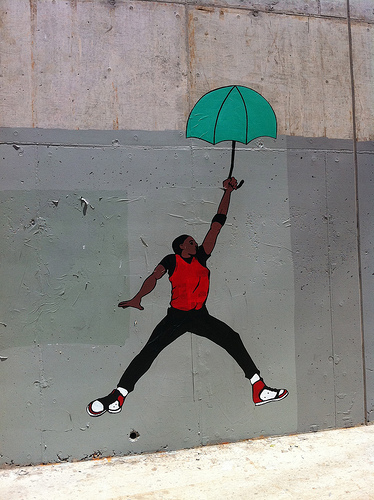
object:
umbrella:
[184, 84, 280, 144]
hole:
[129, 430, 139, 442]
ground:
[55, 459, 301, 497]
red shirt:
[169, 253, 208, 310]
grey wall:
[299, 206, 362, 333]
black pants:
[116, 308, 260, 394]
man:
[86, 176, 291, 419]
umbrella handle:
[227, 163, 246, 191]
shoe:
[250, 377, 289, 406]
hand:
[116, 297, 144, 312]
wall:
[3, 0, 355, 426]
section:
[12, 356, 100, 388]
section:
[82, 165, 183, 221]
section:
[238, 282, 270, 328]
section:
[258, 327, 297, 364]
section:
[338, 295, 373, 372]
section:
[164, 372, 214, 424]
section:
[14, 230, 121, 345]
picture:
[3, 137, 355, 431]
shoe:
[86, 388, 126, 417]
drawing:
[85, 85, 290, 419]